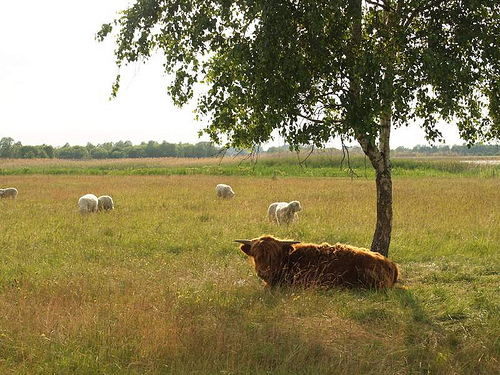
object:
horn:
[232, 236, 251, 249]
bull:
[231, 234, 398, 300]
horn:
[278, 239, 301, 246]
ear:
[282, 245, 296, 252]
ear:
[240, 244, 259, 254]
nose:
[256, 265, 270, 279]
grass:
[125, 303, 157, 338]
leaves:
[103, 72, 127, 107]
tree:
[88, 1, 498, 259]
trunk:
[347, 10, 399, 257]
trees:
[90, 141, 108, 160]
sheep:
[266, 201, 302, 224]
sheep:
[207, 183, 238, 200]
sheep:
[77, 194, 99, 213]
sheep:
[0, 186, 18, 201]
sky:
[0, 0, 88, 117]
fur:
[265, 242, 283, 257]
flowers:
[11, 279, 29, 295]